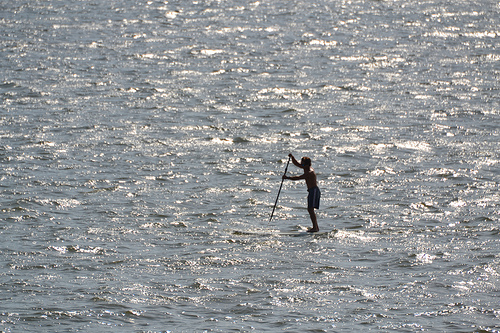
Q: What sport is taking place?
A: Paddleboarding.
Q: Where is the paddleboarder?
A: Ocean.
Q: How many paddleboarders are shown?
A: One.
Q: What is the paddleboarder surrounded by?
A: Water.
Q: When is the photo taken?
A: Daytime.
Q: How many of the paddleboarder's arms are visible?
A: Two.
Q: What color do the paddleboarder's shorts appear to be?
A: Black.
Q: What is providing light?
A: Sun.